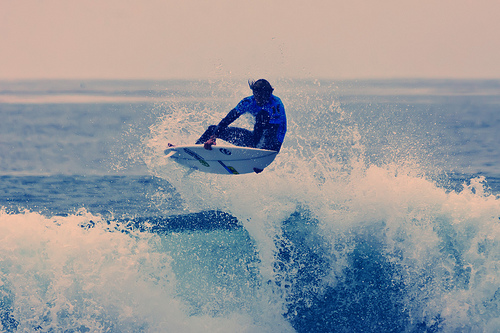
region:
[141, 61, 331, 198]
a man on a surf broad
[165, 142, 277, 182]
a white surf broad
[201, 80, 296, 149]
a man holding on to a sur broad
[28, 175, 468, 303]
a large blue wave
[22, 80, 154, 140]
a ocean in the back ground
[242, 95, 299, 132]
a sky blue top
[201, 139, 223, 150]
the right hand of a surfer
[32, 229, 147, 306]
white foam from the wave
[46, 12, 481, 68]
clear skys over the ocean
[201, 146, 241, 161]
s symbol on the surf broad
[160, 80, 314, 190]
One man surfing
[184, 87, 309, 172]
Blue wet suit on the surfer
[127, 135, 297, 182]
The surfboard is white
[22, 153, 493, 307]
White caps on the wave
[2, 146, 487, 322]
large wave crashing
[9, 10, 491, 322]
Photo taken during the day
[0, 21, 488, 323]
Photo taken at the ocean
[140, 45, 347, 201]
One person in the photo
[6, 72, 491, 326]
The water appears blue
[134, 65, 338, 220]
The surfer catching some air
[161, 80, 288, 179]
man on surf board in the air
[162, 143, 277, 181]
a surfboard in the air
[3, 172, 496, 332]
a wave crashing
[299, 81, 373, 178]
water droplets in the air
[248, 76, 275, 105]
head of a man surfing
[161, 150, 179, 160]
surfboard fin on the base of the board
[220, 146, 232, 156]
logo on a surfboard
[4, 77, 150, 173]
calm ocean water in the distance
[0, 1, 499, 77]
a grey sky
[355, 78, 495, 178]
water droplets in the air and a calm sea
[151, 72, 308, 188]
a surfer in the air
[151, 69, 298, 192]
a surfer holding a surfboard with both hands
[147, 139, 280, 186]
surfboard is color white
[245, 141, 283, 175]
nose of surfboard is pointy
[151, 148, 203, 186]
two fins on back of surfboard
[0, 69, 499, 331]
a wave is forming in the sea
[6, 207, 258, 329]
wave is foamy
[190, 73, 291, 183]
surfer wears a wet suit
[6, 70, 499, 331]
water of ocean is blue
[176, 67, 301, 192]
surfer is crouched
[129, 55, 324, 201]
a surfer performing a stunt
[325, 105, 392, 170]
water spraying into the air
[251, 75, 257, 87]
hair blowing in the wind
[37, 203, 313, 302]
a large wave lifting the man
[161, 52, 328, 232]
a man on a surfboard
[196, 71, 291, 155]
a man wearing a blue and black wetsuit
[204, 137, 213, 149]
a hand gripping the surfboard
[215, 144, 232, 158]
a black logo on the board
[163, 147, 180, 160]
a white fin on the surfboard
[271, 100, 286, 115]
a black logo on the shoulder